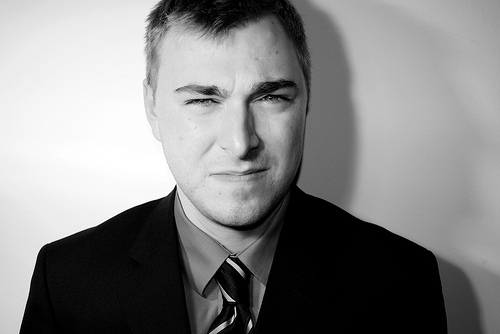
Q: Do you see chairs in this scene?
A: No, there are no chairs.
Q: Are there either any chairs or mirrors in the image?
A: No, there are no chairs or mirrors.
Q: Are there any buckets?
A: No, there are no buckets.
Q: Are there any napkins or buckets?
A: No, there are no buckets or napkins.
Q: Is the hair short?
A: Yes, the hair is short.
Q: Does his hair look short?
A: Yes, the hair is short.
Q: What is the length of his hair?
A: The hair is short.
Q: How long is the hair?
A: The hair is short.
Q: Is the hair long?
A: No, the hair is short.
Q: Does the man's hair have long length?
A: No, the hair is short.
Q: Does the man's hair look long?
A: No, the hair is short.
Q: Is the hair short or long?
A: The hair is short.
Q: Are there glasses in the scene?
A: No, there are no glasses.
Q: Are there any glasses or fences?
A: No, there are no glasses or fences.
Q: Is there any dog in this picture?
A: No, there are no dogs.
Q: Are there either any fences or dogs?
A: No, there are no dogs or fences.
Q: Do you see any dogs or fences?
A: No, there are no dogs or fences.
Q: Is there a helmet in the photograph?
A: No, there are no helmets.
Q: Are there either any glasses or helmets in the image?
A: No, there are no helmets or glasses.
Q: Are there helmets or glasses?
A: No, there are no helmets or glasses.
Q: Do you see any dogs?
A: No, there are no dogs.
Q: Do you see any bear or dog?
A: No, there are no dogs or bears.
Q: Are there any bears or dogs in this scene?
A: No, there are no dogs or bears.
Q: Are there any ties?
A: Yes, there is a tie.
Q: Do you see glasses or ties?
A: Yes, there is a tie.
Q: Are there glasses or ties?
A: Yes, there is a tie.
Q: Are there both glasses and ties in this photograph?
A: No, there is a tie but no glasses.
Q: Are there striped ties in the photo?
A: Yes, there is a striped tie.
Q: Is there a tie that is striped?
A: Yes, there is a tie that is striped.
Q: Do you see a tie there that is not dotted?
A: Yes, there is a striped tie.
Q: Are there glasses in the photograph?
A: No, there are no glasses.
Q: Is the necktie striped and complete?
A: Yes, the necktie is striped and complete.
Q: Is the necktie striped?
A: Yes, the necktie is striped.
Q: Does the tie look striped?
A: Yes, the tie is striped.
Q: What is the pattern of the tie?
A: The tie is striped.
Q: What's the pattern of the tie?
A: The tie is striped.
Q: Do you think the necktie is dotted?
A: No, the necktie is striped.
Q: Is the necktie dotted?
A: No, the necktie is striped.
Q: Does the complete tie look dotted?
A: No, the tie is striped.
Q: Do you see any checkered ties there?
A: No, there is a tie but it is striped.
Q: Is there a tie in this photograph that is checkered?
A: No, there is a tie but it is striped.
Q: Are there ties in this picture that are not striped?
A: No, there is a tie but it is striped.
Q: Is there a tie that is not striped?
A: No, there is a tie but it is striped.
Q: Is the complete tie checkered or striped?
A: The necktie is striped.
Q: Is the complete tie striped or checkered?
A: The necktie is striped.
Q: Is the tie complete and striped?
A: Yes, the tie is complete and striped.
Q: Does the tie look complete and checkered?
A: No, the tie is complete but striped.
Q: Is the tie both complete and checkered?
A: No, the tie is complete but striped.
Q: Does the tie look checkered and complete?
A: No, the tie is complete but striped.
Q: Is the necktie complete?
A: Yes, the necktie is complete.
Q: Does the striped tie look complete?
A: Yes, the tie is complete.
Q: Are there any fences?
A: No, there are no fences.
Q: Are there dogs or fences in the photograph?
A: No, there are no fences or dogs.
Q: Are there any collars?
A: Yes, there is a collar.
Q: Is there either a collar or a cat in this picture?
A: Yes, there is a collar.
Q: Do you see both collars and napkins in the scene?
A: No, there is a collar but no napkins.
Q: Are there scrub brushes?
A: No, there are no scrub brushes.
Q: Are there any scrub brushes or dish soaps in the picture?
A: No, there are no scrub brushes or dish soaps.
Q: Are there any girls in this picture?
A: No, there are no girls.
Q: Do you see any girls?
A: No, there are no girls.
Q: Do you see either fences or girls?
A: No, there are no girls or fences.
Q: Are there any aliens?
A: No, there are no aliens.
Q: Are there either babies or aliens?
A: No, there are no aliens or babies.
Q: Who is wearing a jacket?
A: The man is wearing a jacket.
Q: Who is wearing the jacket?
A: The man is wearing a jacket.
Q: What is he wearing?
A: The man is wearing a jacket.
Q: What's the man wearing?
A: The man is wearing a jacket.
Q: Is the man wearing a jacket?
A: Yes, the man is wearing a jacket.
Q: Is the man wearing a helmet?
A: No, the man is wearing a jacket.